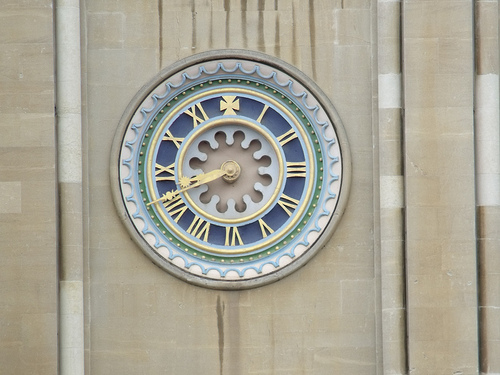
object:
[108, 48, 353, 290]
circle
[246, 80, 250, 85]
dot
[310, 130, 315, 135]
dot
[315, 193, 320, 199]
dot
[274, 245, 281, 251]
dot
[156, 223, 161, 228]
dot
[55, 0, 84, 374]
concrete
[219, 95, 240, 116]
cross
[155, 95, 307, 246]
blue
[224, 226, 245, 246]
numbers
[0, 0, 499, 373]
building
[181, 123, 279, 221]
gear design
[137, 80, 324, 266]
clock face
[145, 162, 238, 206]
minute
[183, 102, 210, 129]
roman numeral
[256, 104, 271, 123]
roman numeral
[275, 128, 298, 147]
roman numeral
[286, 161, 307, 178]
roman numeral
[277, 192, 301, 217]
roman numeral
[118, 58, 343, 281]
design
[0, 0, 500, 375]
wall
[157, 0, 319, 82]
wavy design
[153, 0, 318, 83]
stains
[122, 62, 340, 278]
decoration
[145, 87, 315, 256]
circle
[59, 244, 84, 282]
bricks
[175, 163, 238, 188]
hands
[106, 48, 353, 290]
clock